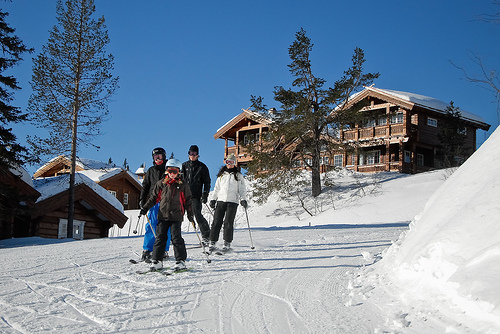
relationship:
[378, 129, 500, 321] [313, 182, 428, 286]
hillside covered with snow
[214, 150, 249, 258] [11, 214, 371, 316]
skier on top of slope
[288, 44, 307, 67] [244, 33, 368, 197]
leaves on tree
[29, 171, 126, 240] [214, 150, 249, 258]
building next to skier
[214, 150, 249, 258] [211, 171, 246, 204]
skier wearing jacket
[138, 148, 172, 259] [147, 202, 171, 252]
skier wearing pants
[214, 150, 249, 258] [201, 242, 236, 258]
skier standing on skies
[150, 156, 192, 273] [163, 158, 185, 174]
skier wearing helmet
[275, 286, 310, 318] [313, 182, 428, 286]
tracks in snow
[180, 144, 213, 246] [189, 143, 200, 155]
skier wearing cap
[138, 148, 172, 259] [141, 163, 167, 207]
skier wearing jacket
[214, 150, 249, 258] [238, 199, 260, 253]
skier holding ski pole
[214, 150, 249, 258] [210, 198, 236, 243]
skier wearing pants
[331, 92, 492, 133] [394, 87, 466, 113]
roof covered in snow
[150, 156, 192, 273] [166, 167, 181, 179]
skier wearing goggles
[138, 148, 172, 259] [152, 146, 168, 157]
skier wearing helmet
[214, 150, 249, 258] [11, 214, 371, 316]
skier skiing down slope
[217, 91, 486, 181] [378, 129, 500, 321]
building on top of hillside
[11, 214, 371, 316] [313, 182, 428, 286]
slope covered snow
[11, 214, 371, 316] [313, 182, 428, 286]
slope covered with snow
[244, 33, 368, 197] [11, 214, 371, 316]
tree on top of slope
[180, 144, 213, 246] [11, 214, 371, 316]
skier skiing down slope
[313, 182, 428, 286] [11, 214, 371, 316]
snow on top of slope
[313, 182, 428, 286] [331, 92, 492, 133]
snow covering roof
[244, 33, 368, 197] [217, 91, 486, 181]
tree in front of building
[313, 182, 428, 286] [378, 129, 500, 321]
snow on hillside